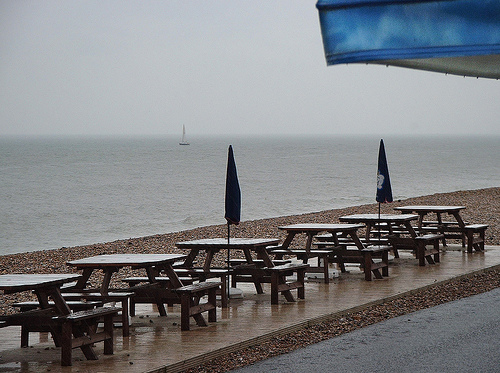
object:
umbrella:
[373, 136, 390, 246]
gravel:
[383, 294, 413, 318]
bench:
[264, 263, 310, 305]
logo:
[377, 170, 385, 189]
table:
[0, 273, 100, 360]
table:
[61, 253, 208, 349]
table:
[175, 238, 297, 306]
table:
[273, 223, 384, 280]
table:
[339, 213, 435, 264]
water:
[0, 136, 500, 258]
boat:
[179, 123, 190, 145]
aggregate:
[147, 264, 499, 371]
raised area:
[1, 186, 498, 371]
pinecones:
[172, 322, 177, 326]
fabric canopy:
[316, 0, 498, 78]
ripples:
[30, 175, 176, 227]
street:
[299, 277, 497, 370]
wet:
[248, 296, 342, 338]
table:
[392, 204, 485, 254]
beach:
[0, 186, 499, 326]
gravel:
[138, 238, 172, 252]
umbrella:
[222, 145, 244, 226]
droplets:
[386, 64, 390, 67]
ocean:
[0, 135, 500, 200]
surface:
[9, 188, 498, 369]